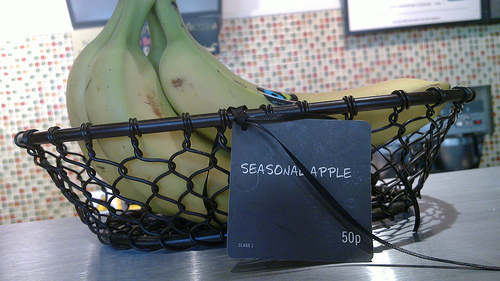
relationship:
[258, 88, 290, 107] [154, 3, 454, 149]
label on banana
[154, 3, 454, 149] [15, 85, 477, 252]
banana in basket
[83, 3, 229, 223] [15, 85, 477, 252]
banana in basket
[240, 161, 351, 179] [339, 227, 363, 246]
writing for 50p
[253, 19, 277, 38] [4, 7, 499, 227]
tile on wall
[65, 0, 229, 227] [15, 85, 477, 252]
banana in basket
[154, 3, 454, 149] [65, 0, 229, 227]
banana in banana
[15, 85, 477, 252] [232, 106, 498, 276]
basket has string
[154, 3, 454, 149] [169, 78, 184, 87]
banana has bruise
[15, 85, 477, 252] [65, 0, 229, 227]
basket holding banana